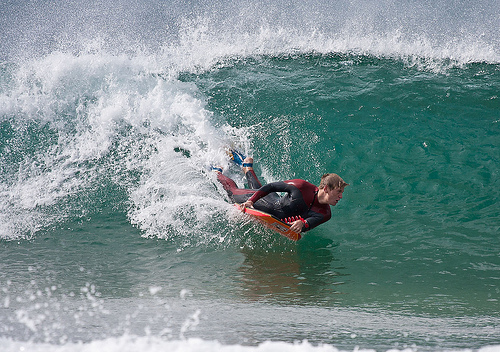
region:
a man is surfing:
[165, 103, 319, 255]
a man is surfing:
[87, 102, 256, 342]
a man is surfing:
[161, 26, 370, 334]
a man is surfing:
[202, 147, 364, 344]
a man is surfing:
[179, 123, 311, 344]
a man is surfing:
[200, 109, 327, 336]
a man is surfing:
[205, 148, 336, 348]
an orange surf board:
[232, 193, 302, 243]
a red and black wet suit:
[212, 165, 329, 232]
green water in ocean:
[350, 146, 456, 186]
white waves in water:
[0, 20, 280, 225]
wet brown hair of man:
[315, 170, 345, 190]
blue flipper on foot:
[220, 140, 255, 161]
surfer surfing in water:
[205, 142, 346, 238]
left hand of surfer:
[287, 218, 307, 234]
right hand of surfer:
[237, 198, 256, 210]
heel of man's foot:
[241, 156, 254, 168]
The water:
[303, 263, 385, 347]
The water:
[316, 294, 362, 338]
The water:
[321, 270, 367, 334]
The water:
[334, 294, 420, 345]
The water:
[364, 296, 387, 326]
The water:
[380, 329, 415, 350]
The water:
[289, 293, 334, 341]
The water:
[327, 256, 442, 349]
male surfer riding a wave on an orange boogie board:
[185, 132, 355, 250]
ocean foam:
[4, 0, 499, 65]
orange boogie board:
[227, 197, 314, 245]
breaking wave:
[2, 21, 257, 165]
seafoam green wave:
[355, 113, 497, 184]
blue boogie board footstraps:
[205, 139, 259, 178]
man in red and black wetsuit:
[210, 167, 347, 232]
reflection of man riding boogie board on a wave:
[230, 230, 345, 309]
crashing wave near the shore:
[3, 268, 428, 350]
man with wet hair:
[309, 163, 353, 216]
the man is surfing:
[121, 118, 456, 332]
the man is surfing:
[226, 135, 371, 307]